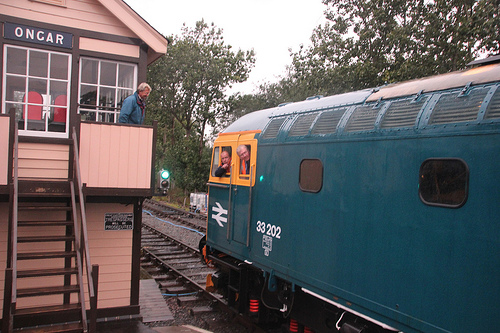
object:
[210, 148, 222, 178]
train windows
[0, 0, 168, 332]
train stop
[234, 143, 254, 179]
window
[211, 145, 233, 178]
person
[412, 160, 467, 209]
window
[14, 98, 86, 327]
entrance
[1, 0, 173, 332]
house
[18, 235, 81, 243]
steps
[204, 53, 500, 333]
train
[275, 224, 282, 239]
number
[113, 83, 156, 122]
person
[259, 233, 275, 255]
symbol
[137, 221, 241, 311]
rail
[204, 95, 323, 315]
last part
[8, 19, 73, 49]
sign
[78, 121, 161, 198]
balcony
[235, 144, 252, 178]
men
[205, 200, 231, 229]
logo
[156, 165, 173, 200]
traffic light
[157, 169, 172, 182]
green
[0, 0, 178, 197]
second floor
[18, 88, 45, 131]
chair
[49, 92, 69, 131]
chair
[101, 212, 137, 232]
sign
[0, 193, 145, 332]
first floor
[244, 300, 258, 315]
springs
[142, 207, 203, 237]
blue chord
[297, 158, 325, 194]
window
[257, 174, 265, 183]
green light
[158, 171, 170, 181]
green light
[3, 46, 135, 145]
waiting area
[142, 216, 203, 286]
rusty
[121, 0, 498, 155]
sky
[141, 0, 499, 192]
trees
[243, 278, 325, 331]
shocks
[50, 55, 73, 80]
window